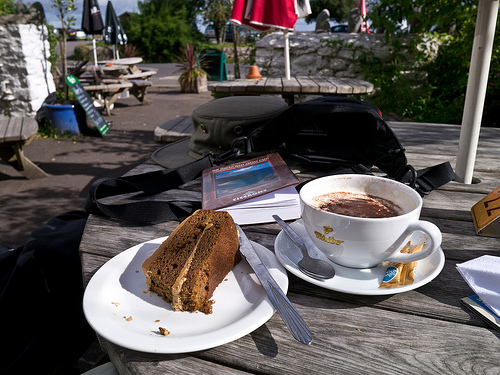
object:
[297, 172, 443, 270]
coffee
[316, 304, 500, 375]
surface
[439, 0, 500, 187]
pole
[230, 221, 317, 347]
knife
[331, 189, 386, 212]
hot chocolate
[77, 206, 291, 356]
plate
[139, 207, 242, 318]
cake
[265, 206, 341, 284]
spoon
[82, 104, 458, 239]
bag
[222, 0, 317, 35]
umbrella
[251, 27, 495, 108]
stone wall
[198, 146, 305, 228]
white hook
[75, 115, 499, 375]
round tables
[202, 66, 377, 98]
round tables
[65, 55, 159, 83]
round tables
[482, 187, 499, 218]
number 22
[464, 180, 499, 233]
sign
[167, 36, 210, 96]
plants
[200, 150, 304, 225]
book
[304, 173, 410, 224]
liquid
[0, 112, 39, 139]
area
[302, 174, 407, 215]
cup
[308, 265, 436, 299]
saucer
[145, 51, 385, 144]
patio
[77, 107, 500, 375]
table